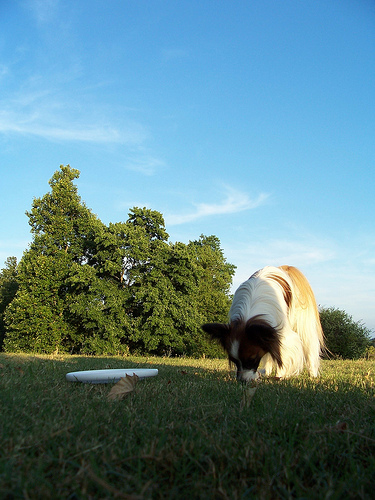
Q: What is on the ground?
A: Frisbee.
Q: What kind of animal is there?
A: Dog.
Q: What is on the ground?
A: Shadow.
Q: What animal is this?
A: Dog.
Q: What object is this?
A: Tree.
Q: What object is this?
A: Grass.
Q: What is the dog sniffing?
A: Grass.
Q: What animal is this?
A: Dog.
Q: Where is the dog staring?
A: Ground.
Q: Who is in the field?
A: A dog.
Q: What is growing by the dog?
A: Grass.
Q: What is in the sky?
A: Clouds.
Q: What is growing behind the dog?
A: Trees.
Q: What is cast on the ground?
A: A shadow.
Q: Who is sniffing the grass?
A: A dog.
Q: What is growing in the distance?
A: Trees.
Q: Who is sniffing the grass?
A: A dog.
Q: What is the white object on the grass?
A: A frisbee.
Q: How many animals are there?
A: One.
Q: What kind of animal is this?
A: A dog.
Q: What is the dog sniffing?
A: The grass.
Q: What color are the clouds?
A: White.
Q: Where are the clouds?
A: In the sky.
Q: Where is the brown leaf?
A: Next to the frisbee.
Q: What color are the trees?
A: Green.